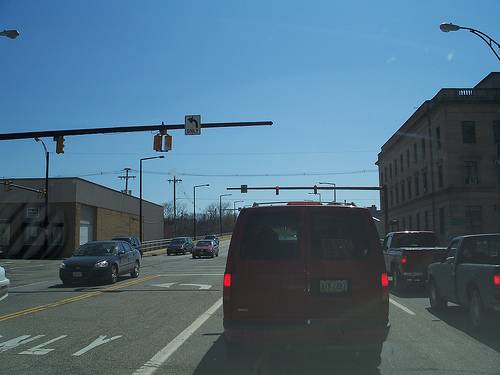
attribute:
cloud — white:
[446, 48, 454, 61]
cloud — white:
[389, 52, 397, 67]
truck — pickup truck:
[383, 230, 446, 290]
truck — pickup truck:
[428, 232, 495, 327]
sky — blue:
[0, 1, 497, 216]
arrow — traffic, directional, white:
[151, 280, 212, 291]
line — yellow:
[3, 254, 159, 344]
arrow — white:
[143, 272, 226, 314]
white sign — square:
[182, 114, 201, 134]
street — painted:
[34, 277, 189, 374]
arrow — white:
[147, 255, 224, 317]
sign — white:
[182, 112, 203, 137]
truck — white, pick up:
[424, 232, 499, 327]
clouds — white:
[69, 49, 237, 123]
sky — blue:
[300, 99, 335, 153]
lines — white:
[1, 267, 238, 372]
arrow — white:
[149, 277, 214, 292]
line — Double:
[2, 274, 162, 321]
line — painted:
[131, 294, 224, 373]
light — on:
[223, 273, 231, 283]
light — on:
[380, 272, 388, 286]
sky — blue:
[91, 22, 398, 96]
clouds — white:
[361, 25, 466, 72]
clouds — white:
[329, 21, 433, 79]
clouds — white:
[284, 19, 456, 81]